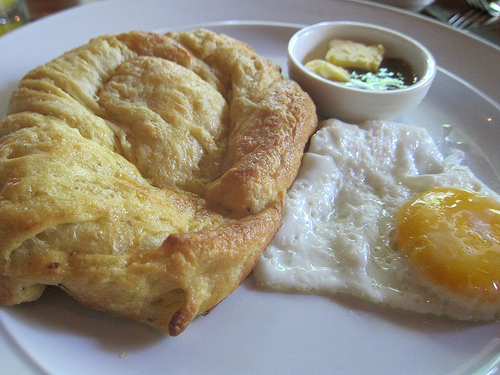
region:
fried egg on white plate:
[296, 105, 494, 292]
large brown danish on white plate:
[31, 25, 271, 335]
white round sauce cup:
[288, 12, 433, 113]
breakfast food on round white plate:
[10, 10, 497, 343]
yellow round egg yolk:
[395, 180, 497, 274]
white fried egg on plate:
[301, 117, 396, 302]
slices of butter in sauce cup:
[303, 27, 389, 89]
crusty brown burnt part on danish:
[153, 272, 207, 348]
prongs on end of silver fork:
[442, 6, 499, 45]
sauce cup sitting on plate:
[278, 2, 450, 136]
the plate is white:
[6, 44, 348, 328]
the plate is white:
[103, 73, 411, 372]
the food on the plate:
[11, 26, 498, 344]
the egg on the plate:
[257, 106, 497, 324]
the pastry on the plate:
[2, 14, 317, 335]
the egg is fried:
[245, 117, 499, 315]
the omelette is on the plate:
[243, 115, 499, 326]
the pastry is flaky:
[40, 45, 298, 316]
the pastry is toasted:
[18, 39, 318, 329]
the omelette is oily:
[16, 14, 490, 364]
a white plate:
[21, 8, 497, 372]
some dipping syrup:
[295, 13, 430, 122]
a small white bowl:
[284, 17, 447, 128]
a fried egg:
[265, 117, 497, 342]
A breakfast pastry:
[0, 21, 336, 326]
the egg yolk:
[388, 180, 494, 304]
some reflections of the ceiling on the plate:
[428, 100, 497, 156]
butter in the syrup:
[305, 25, 384, 90]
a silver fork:
[446, 0, 493, 39]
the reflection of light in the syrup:
[326, 42, 408, 96]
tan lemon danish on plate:
[89, 57, 249, 172]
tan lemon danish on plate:
[25, 153, 200, 278]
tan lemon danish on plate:
[77, 47, 208, 291]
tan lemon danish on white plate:
[67, 61, 199, 267]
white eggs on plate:
[318, 138, 378, 253]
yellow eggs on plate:
[357, 141, 484, 292]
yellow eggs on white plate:
[301, 142, 486, 343]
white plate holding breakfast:
[228, 312, 335, 363]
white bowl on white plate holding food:
[290, 11, 425, 111]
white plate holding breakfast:
[185, 5, 250, 50]